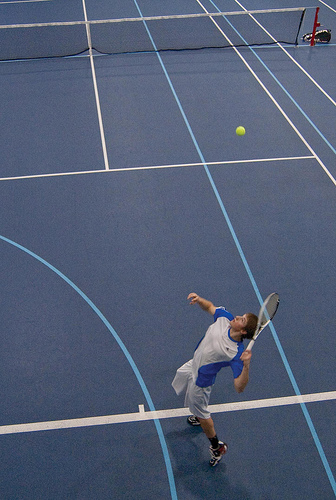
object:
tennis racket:
[238, 288, 282, 358]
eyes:
[239, 315, 245, 326]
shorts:
[171, 356, 215, 421]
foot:
[207, 438, 227, 466]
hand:
[185, 290, 198, 306]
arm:
[197, 295, 226, 319]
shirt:
[189, 304, 246, 389]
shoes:
[205, 437, 229, 471]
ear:
[239, 328, 248, 336]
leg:
[185, 387, 218, 449]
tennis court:
[0, 0, 335, 499]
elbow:
[234, 381, 250, 393]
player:
[171, 291, 258, 473]